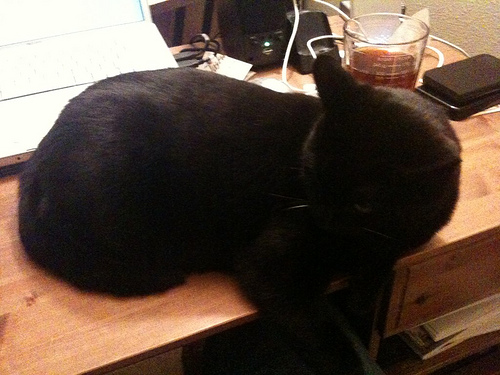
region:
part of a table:
[61, 311, 120, 340]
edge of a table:
[168, 315, 195, 330]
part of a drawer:
[413, 313, 432, 349]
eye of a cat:
[363, 190, 377, 205]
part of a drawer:
[443, 273, 450, 284]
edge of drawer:
[413, 286, 453, 326]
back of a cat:
[36, 179, 81, 210]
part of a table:
[206, 306, 242, 335]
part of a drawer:
[369, 307, 386, 352]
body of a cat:
[148, 248, 171, 275]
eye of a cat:
[361, 204, 368, 212]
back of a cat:
[118, 263, 137, 305]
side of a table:
[148, 328, 177, 350]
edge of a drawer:
[420, 285, 454, 305]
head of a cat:
[341, 181, 363, 217]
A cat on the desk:
[39, 65, 454, 285]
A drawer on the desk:
[406, 237, 492, 317]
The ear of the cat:
[313, 61, 356, 104]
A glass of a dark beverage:
[341, 12, 421, 87]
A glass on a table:
[343, 11, 421, 89]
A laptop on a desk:
[6, 0, 179, 67]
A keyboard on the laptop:
[6, 33, 173, 72]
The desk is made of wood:
[24, 318, 195, 345]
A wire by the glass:
[286, 24, 295, 87]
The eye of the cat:
[353, 197, 371, 214]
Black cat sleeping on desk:
[17, 89, 494, 329]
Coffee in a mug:
[336, 20, 441, 97]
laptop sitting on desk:
[1, 5, 171, 170]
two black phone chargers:
[193, 4, 345, 79]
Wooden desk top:
[8, 27, 498, 374]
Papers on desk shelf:
[403, 272, 499, 354]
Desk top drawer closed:
[392, 231, 495, 341]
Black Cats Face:
[291, 71, 456, 258]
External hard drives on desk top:
[415, 60, 495, 135]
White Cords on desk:
[268, 4, 481, 96]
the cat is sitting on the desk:
[19, 48, 466, 360]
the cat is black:
[10, 58, 474, 369]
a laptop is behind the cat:
[2, 2, 182, 141]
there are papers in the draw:
[427, 301, 499, 338]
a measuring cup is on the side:
[342, 16, 432, 96]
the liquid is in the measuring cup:
[344, 59, 421, 91]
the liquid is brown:
[347, 51, 422, 95]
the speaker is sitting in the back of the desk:
[218, 1, 290, 70]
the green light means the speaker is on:
[262, 41, 271, 50]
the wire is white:
[280, 1, 303, 88]